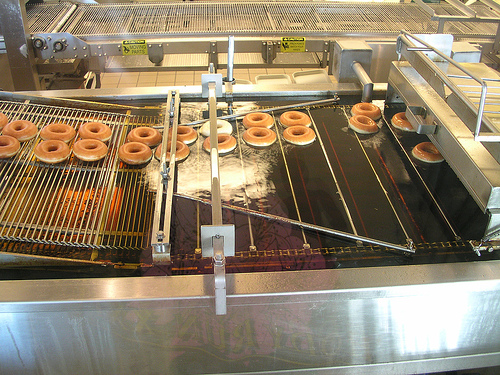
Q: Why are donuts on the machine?
A: Because it is a donut maker.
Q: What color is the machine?
A: The machine is silver.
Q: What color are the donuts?
A: The donuts are brown.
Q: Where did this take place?
A: It took place at a donut shop.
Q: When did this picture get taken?
A: It was taken in the day time.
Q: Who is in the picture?
A: Nobody is in the picture.